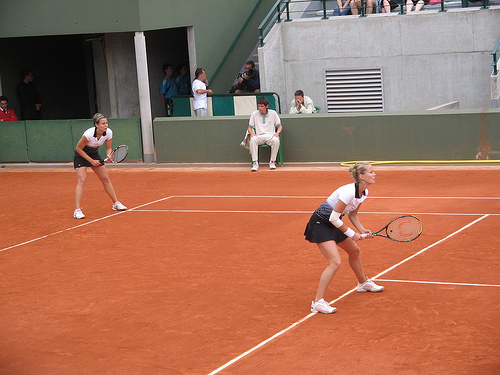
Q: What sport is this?
A: Tennis.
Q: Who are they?
A: Players.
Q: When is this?
A: Daytime.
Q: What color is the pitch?
A: Brown.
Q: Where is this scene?
A: On tennis court.